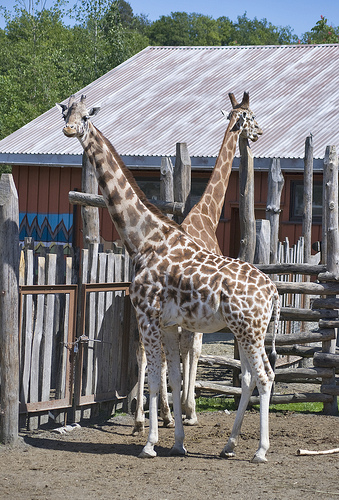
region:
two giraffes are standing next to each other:
[52, 86, 281, 464]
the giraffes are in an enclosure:
[7, 93, 337, 496]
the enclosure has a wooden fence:
[2, 138, 338, 496]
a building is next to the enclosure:
[2, 38, 338, 261]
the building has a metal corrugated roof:
[7, 36, 337, 167]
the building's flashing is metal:
[1, 148, 338, 179]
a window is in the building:
[285, 177, 328, 227]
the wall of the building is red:
[13, 167, 336, 258]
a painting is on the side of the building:
[16, 211, 79, 295]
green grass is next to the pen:
[177, 384, 338, 418]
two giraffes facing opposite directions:
[50, 86, 278, 254]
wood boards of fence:
[24, 253, 68, 394]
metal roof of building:
[141, 58, 198, 113]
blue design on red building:
[30, 201, 61, 236]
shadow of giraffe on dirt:
[36, 430, 180, 460]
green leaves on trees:
[0, 41, 71, 95]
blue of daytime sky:
[268, 3, 311, 22]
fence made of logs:
[281, 260, 328, 403]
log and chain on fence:
[58, 334, 85, 371]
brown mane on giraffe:
[118, 160, 145, 199]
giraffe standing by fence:
[56, 97, 279, 460]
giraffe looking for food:
[183, 99, 265, 249]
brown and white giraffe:
[57, 95, 277, 464]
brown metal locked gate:
[20, 281, 133, 423]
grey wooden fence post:
[323, 147, 338, 410]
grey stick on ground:
[294, 445, 337, 452]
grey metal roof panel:
[1, 42, 338, 161]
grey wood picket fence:
[20, 246, 126, 426]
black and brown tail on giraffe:
[270, 293, 280, 370]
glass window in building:
[290, 179, 327, 221]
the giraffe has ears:
[31, 106, 226, 196]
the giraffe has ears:
[42, 61, 141, 167]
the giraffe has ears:
[48, 94, 110, 142]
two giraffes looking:
[42, 41, 279, 460]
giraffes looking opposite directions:
[1, 63, 276, 381]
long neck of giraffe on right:
[161, 70, 284, 265]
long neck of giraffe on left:
[40, 110, 178, 264]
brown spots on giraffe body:
[133, 244, 240, 326]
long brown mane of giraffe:
[105, 95, 183, 233]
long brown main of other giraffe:
[179, 132, 244, 231]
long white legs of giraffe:
[49, 299, 283, 454]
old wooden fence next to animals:
[0, 232, 114, 399]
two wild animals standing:
[0, 69, 293, 397]